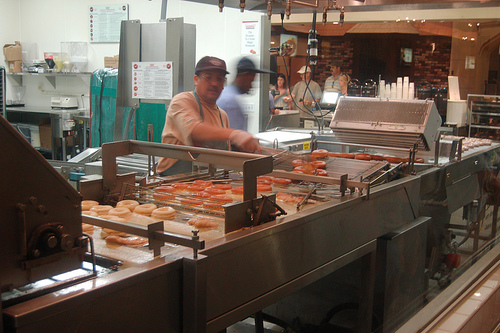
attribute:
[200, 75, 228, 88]
man — wearing glasses, wearing apron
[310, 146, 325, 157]
doughnuts — traveling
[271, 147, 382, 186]
tray — silver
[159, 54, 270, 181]
man — wearing hat, making doughnuts, wearing gloves, wearing shirt, wearing t-shirt, wearing apron, wearing glasses, standing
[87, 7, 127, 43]
sign — rectangle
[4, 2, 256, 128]
wall — white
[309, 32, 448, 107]
entrance — brick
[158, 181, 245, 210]
doughnuts — glazed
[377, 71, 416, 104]
cups — white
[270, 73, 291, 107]
customer — female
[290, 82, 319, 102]
shirt — gray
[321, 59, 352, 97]
man — tall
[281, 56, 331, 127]
wire — electrical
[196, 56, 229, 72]
hat — black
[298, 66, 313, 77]
hat — white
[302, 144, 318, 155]
label — yellow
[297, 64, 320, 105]
person — standing